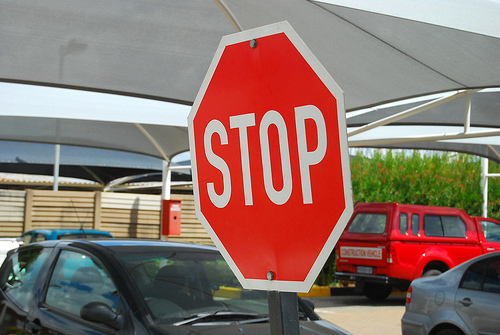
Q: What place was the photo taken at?
A: It was taken at the parking lot.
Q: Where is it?
A: This is at the parking lot.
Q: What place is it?
A: It is a parking lot.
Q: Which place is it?
A: It is a parking lot.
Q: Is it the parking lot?
A: Yes, it is the parking lot.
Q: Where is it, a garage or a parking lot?
A: It is a parking lot.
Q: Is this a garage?
A: No, it is a parking lot.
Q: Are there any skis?
A: No, there are no skis.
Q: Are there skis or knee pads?
A: No, there are no skis or knee pads.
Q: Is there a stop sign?
A: Yes, there is a stop sign.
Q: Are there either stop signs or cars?
A: Yes, there is a stop sign.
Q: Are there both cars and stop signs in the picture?
A: Yes, there are both a stop sign and a car.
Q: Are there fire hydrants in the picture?
A: No, there are no fire hydrants.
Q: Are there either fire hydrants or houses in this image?
A: No, there are no fire hydrants or houses.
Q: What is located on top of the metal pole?
A: The stop sign is on top of the pole.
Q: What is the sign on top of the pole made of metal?
A: The sign is a stop sign.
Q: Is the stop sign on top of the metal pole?
A: Yes, the stop sign is on top of the pole.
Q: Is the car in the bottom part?
A: Yes, the car is in the bottom of the image.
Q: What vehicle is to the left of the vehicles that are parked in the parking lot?
A: The vehicle is a car.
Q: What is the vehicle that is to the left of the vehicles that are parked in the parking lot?
A: The vehicle is a car.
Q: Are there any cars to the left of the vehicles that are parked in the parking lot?
A: Yes, there is a car to the left of the vehicles.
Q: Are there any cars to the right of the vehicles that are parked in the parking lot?
A: No, the car is to the left of the vehicles.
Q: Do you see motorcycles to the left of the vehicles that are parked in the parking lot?
A: No, there is a car to the left of the vehicles.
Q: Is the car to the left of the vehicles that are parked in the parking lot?
A: Yes, the car is to the left of the vehicles.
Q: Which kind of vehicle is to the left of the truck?
A: The vehicle is a car.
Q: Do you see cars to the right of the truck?
A: No, the car is to the left of the truck.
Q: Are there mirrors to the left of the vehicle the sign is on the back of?
A: No, there is a car to the left of the truck.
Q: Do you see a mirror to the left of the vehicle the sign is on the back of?
A: No, there is a car to the left of the truck.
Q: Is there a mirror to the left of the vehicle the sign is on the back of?
A: No, there is a car to the left of the truck.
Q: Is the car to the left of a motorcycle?
A: No, the car is to the left of the truck.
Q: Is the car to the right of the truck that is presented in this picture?
A: No, the car is to the left of the truck.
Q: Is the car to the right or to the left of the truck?
A: The car is to the left of the truck.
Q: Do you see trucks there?
A: Yes, there is a truck.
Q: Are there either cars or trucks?
A: Yes, there is a truck.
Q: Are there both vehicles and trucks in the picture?
A: Yes, there are both a truck and a vehicle.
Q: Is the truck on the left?
A: No, the truck is on the right of the image.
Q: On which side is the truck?
A: The truck is on the right of the image.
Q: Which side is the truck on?
A: The truck is on the right of the image.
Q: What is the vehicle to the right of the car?
A: The vehicle is a truck.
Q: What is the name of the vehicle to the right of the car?
A: The vehicle is a truck.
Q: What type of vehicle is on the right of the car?
A: The vehicle is a truck.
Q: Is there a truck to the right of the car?
A: Yes, there is a truck to the right of the car.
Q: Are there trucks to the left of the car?
A: No, the truck is to the right of the car.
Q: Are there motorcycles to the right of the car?
A: No, there is a truck to the right of the car.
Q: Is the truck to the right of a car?
A: Yes, the truck is to the right of a car.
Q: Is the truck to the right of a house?
A: No, the truck is to the right of a car.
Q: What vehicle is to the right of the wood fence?
A: The vehicle is a truck.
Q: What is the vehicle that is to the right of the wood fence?
A: The vehicle is a truck.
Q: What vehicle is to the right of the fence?
A: The vehicle is a truck.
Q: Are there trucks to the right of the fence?
A: Yes, there is a truck to the right of the fence.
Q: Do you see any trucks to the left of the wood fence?
A: No, the truck is to the right of the fence.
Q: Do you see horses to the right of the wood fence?
A: No, there is a truck to the right of the fence.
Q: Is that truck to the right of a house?
A: No, the truck is to the right of a fence.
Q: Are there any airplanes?
A: No, there are no airplanes.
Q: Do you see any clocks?
A: No, there are no clocks.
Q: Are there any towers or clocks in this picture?
A: No, there are no clocks or towers.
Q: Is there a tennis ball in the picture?
A: No, there are no tennis balls.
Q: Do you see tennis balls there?
A: No, there are no tennis balls.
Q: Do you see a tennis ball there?
A: No, there are no tennis balls.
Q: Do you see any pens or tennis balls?
A: No, there are no tennis balls or pens.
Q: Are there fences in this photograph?
A: Yes, there is a fence.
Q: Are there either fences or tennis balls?
A: Yes, there is a fence.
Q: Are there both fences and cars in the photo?
A: Yes, there are both a fence and a car.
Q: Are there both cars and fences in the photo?
A: Yes, there are both a fence and a car.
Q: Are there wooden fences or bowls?
A: Yes, there is a wood fence.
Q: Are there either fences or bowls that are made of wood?
A: Yes, the fence is made of wood.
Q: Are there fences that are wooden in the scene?
A: Yes, there is a wood fence.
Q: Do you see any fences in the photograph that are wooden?
A: Yes, there is a fence that is wooden.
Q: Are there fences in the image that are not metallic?
A: Yes, there is a wooden fence.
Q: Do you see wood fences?
A: Yes, there is a fence that is made of wood.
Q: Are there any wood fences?
A: Yes, there is a fence that is made of wood.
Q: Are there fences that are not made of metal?
A: Yes, there is a fence that is made of wood.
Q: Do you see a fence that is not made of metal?
A: Yes, there is a fence that is made of wood.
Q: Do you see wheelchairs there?
A: No, there are no wheelchairs.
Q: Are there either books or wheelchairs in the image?
A: No, there are no wheelchairs or books.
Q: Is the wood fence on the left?
A: Yes, the fence is on the left of the image.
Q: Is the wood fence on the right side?
A: No, the fence is on the left of the image.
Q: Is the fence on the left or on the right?
A: The fence is on the left of the image.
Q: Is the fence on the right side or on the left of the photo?
A: The fence is on the left of the image.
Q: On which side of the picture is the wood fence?
A: The fence is on the left of the image.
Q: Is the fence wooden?
A: Yes, the fence is wooden.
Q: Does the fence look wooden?
A: Yes, the fence is wooden.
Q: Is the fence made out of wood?
A: Yes, the fence is made of wood.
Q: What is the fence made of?
A: The fence is made of wood.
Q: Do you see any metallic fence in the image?
A: No, there is a fence but it is wooden.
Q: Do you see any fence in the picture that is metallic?
A: No, there is a fence but it is wooden.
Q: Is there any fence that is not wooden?
A: No, there is a fence but it is wooden.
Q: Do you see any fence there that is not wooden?
A: No, there is a fence but it is wooden.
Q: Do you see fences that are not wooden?
A: No, there is a fence but it is wooden.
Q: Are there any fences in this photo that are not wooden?
A: No, there is a fence but it is wooden.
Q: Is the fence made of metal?
A: No, the fence is made of wood.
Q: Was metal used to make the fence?
A: No, the fence is made of wood.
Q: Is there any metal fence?
A: No, there is a fence but it is made of wood.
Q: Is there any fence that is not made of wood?
A: No, there is a fence but it is made of wood.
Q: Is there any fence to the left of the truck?
A: Yes, there is a fence to the left of the truck.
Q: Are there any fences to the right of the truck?
A: No, the fence is to the left of the truck.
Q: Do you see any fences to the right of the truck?
A: No, the fence is to the left of the truck.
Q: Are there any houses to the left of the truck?
A: No, there is a fence to the left of the truck.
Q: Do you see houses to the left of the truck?
A: No, there is a fence to the left of the truck.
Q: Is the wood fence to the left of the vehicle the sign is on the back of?
A: Yes, the fence is to the left of the truck.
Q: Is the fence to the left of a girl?
A: No, the fence is to the left of the truck.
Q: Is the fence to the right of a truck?
A: No, the fence is to the left of a truck.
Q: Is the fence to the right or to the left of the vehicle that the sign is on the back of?
A: The fence is to the left of the truck.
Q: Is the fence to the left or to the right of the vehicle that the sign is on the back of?
A: The fence is to the left of the truck.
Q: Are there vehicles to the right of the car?
A: Yes, there are vehicles to the right of the car.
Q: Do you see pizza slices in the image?
A: No, there are no pizza slices.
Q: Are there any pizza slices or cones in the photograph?
A: No, there are no pizza slices or cones.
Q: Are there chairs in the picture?
A: No, there are no chairs.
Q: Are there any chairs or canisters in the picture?
A: No, there are no chairs or canisters.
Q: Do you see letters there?
A: Yes, there are letters.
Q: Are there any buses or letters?
A: Yes, there are letters.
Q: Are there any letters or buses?
A: Yes, there are letters.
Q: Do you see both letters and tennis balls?
A: No, there are letters but no tennis balls.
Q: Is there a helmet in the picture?
A: No, there are no helmets.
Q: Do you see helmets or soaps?
A: No, there are no helmets or soaps.